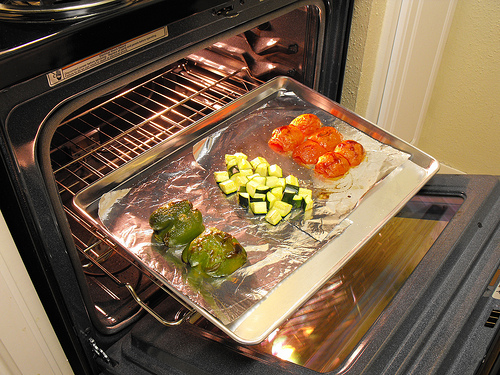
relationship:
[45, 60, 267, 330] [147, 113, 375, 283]
rack holds food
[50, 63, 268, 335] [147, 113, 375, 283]
rack holds food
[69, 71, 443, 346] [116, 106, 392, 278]
pan has covering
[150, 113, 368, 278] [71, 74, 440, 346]
food on tray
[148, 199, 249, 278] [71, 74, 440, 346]
friuts on tray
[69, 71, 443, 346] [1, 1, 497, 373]
pan in oven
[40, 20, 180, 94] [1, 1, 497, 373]
label in oven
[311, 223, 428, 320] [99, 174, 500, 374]
glass on door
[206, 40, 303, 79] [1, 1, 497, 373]
light on in oven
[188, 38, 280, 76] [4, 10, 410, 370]
light in oven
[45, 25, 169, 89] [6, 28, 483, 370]
label in oven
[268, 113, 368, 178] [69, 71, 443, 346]
pan on pan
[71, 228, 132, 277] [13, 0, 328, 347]
burner unit inside oven